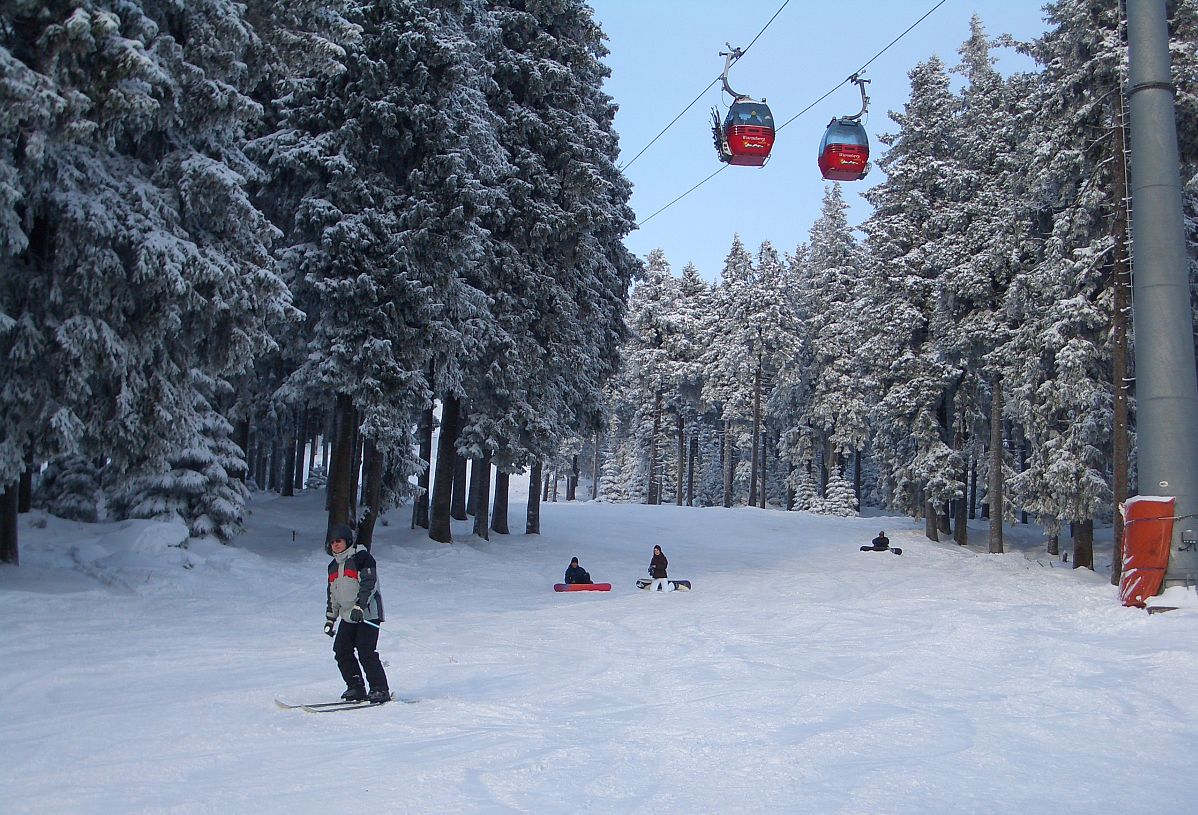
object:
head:
[324, 523, 355, 557]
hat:
[326, 524, 355, 547]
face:
[329, 534, 346, 554]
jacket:
[324, 542, 384, 625]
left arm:
[350, 550, 378, 623]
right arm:
[322, 558, 341, 638]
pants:
[333, 618, 392, 703]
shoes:
[340, 687, 392, 704]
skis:
[271, 697, 424, 713]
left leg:
[354, 619, 391, 703]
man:
[324, 525, 391, 703]